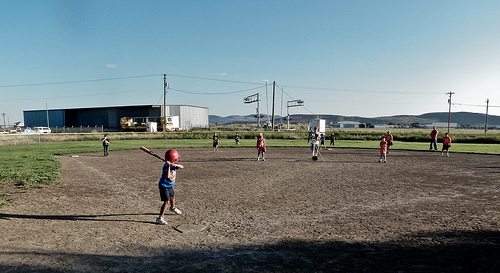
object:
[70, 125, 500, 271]
baseball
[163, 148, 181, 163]
baseball helmet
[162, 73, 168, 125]
powerline pole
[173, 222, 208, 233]
home base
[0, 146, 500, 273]
baseball field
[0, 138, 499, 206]
grass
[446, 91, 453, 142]
telephone pole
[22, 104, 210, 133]
warehouse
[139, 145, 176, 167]
baseball bat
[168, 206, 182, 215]
tennis shoe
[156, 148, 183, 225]
child